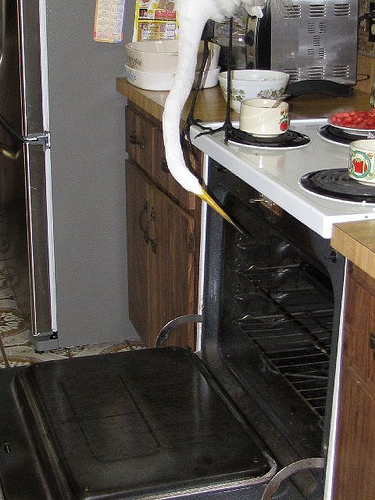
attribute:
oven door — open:
[1, 170, 351, 499]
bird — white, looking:
[162, 0, 264, 237]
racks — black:
[235, 239, 314, 367]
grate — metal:
[234, 302, 341, 436]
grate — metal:
[233, 252, 338, 362]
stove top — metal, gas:
[198, 109, 374, 224]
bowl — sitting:
[213, 61, 293, 109]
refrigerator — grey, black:
[0, 0, 175, 352]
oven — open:
[183, 142, 337, 467]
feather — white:
[178, 2, 234, 23]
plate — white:
[326, 116, 374, 135]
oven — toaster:
[215, 0, 357, 98]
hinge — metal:
[258, 449, 332, 498]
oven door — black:
[0, 344, 308, 498]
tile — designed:
[0, 340, 72, 367]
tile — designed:
[0, 295, 30, 342]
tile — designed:
[0, 259, 15, 300]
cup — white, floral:
[234, 98, 290, 139]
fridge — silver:
[27, 35, 69, 212]